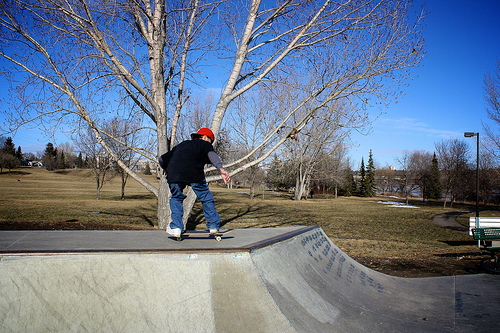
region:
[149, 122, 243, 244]
a skateboarder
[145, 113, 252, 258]
a skateboarder about to perform a trick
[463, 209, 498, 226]
a white park bench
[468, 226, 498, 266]
a green park bench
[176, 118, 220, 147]
a young man wearing a red cap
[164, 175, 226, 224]
a young man wearing blue jeans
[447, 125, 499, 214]
a streetlamp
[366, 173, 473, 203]
a river hidden by trees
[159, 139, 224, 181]
a blue and gray sweater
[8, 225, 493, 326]
a skateboard ramp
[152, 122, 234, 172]
a boy wearing a red cap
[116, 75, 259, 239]
a boy wearing a red cap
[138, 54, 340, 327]
a boy wearing a red cap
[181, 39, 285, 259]
a boy wearing a red cap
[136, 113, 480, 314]
skateboarder on a skateboarding ramp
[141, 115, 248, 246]
skateboarder on a skateboard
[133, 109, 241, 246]
boy on a skateboard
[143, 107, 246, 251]
boy wearing a red hat on a skateboard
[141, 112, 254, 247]
boy wearing a black shirt on a skateboard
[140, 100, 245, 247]
boy wearing white tennis shoes on a skateboard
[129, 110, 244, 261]
boy wearing blue jeans on a skateboard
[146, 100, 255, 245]
boy wearing a long sleeved shirt on a skateboard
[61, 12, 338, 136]
tree in the background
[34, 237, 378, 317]
concrete skateboarding ramp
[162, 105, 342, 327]
a kid in black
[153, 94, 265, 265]
a kid in black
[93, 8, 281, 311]
a kid in black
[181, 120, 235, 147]
a red hat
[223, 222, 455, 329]
a skateboard ramp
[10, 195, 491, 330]
cement skateboard park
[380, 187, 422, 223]
pile of snow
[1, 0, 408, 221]
a tall dead tree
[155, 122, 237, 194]
a black tee shirt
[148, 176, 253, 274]
a kid wearing blue jeans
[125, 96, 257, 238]
a kid skateboarding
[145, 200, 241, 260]
white skating shoes on a skateboard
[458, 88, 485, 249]
a light post in the grass